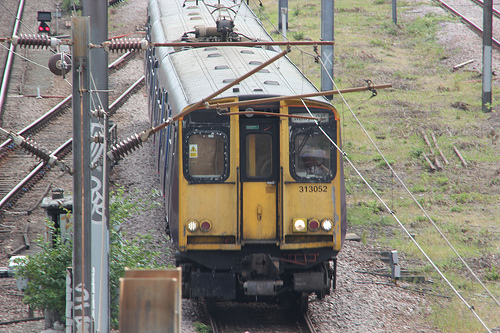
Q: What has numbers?
A: Front of yellow train.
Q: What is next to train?
A: Grassy field.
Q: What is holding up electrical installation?
A: A pole.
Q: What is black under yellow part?
A: Bottom front of train.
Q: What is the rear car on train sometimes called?
A: Caboose.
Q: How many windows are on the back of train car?
A: 3.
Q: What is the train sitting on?
A: Tracks.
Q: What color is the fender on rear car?
A: Dark gray.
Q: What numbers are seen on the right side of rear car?
A: 313052.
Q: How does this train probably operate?
A: By electricity.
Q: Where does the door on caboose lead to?
A: Inside of train.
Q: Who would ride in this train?
A: Travelers.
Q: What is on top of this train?
A: Phone lines.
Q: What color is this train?
A: Yellow.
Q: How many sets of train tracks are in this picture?
A: Three.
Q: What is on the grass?
A: Pieces of wood.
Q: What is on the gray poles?
A: Graffiti.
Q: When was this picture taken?
A: Daytime.